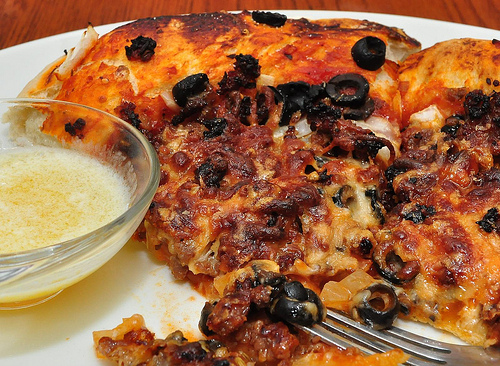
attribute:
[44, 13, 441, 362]
pizza — black olive, parts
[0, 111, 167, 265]
bowl — glass, clear, small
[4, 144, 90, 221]
butter — melted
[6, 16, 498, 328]
table — brown, wood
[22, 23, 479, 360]
plate — white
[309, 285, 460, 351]
fork — silver, metal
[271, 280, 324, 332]
olives — black, many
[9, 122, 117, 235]
sauce — red, yellowish-whitish, butter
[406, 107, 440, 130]
onions — diced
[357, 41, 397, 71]
olive — black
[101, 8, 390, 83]
crust — burnt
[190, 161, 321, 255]
cheese — melted, burnt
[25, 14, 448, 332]
food — black, red, half eaten